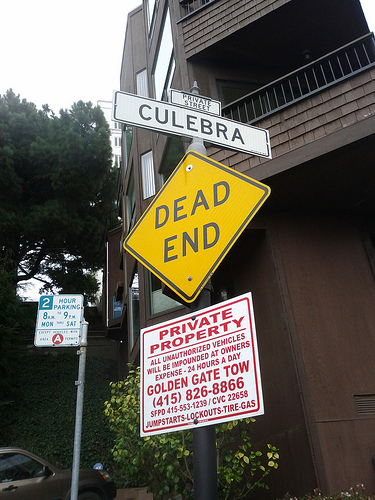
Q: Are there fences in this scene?
A: No, there are no fences.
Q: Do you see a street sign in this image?
A: Yes, there is a street sign.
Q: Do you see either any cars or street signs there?
A: Yes, there is a street sign.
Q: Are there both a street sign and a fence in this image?
A: No, there is a street sign but no fences.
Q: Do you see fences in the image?
A: No, there are no fences.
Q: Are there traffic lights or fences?
A: No, there are no fences or traffic lights.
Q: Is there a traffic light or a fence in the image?
A: No, there are no fences or traffic lights.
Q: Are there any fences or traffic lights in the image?
A: No, there are no fences or traffic lights.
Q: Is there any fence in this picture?
A: No, there are no fences.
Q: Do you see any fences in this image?
A: No, there are no fences.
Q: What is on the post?
A: The sign is on the post.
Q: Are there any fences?
A: No, there are no fences.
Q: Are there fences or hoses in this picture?
A: No, there are no fences or hoses.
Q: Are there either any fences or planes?
A: No, there are no fences or planes.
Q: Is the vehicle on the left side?
A: Yes, the vehicle is on the left of the image.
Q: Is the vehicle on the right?
A: No, the vehicle is on the left of the image.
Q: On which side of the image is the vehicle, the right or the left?
A: The vehicle is on the left of the image.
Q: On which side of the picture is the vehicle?
A: The vehicle is on the left of the image.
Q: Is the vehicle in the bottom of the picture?
A: Yes, the vehicle is in the bottom of the image.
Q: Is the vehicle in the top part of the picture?
A: No, the vehicle is in the bottom of the image.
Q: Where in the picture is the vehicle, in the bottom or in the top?
A: The vehicle is in the bottom of the image.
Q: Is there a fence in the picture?
A: No, there are no fences.